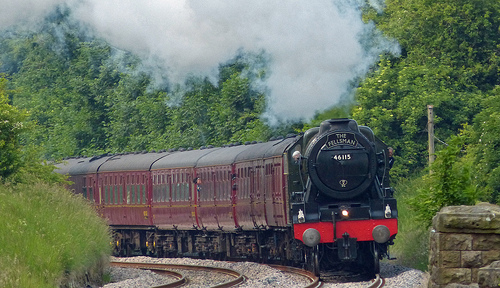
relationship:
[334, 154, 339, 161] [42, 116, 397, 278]
number on train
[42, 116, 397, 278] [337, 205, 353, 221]
train has light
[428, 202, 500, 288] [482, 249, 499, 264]
wall has brick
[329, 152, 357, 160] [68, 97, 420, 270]
numbers on train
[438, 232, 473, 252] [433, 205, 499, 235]
brick of stone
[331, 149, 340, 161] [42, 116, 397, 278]
white number painted on train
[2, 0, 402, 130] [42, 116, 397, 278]
smoke from train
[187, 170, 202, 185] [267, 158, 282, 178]
head out window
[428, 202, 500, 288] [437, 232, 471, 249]
wall has brick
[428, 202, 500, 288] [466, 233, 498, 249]
wall has brick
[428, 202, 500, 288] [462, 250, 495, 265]
wall has stone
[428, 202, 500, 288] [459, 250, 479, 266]
wall has brick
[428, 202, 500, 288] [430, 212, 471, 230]
wall has brick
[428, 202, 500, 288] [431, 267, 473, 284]
wall has brick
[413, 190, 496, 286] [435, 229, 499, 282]
wall has brick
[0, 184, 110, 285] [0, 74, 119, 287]
grass on hill